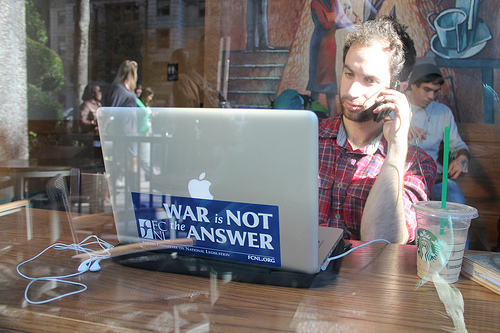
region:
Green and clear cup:
[405, 94, 485, 330]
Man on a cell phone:
[329, 15, 421, 189]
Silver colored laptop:
[90, 83, 337, 300]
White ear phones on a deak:
[16, 216, 136, 323]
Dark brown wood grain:
[400, 309, 417, 327]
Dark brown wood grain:
[348, 309, 378, 327]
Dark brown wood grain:
[363, 266, 406, 303]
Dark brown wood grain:
[287, 299, 332, 329]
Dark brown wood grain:
[248, 290, 297, 322]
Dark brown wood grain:
[173, 295, 241, 331]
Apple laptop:
[94, 103, 345, 287]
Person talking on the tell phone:
[317, 19, 438, 249]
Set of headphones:
[17, 228, 112, 305]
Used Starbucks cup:
[417, 122, 475, 287]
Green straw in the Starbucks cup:
[440, 123, 448, 244]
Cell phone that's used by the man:
[374, 78, 404, 119]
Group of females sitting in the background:
[70, 56, 154, 173]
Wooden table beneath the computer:
[1, 208, 498, 330]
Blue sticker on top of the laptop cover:
[127, 192, 282, 267]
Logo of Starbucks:
[412, 228, 440, 262]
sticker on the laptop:
[130, 188, 287, 268]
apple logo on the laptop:
[183, 167, 227, 204]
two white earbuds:
[12, 228, 118, 308]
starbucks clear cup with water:
[412, 120, 474, 291]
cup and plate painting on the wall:
[429, 10, 485, 61]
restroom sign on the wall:
[164, 60, 178, 82]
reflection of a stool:
[6, 158, 84, 238]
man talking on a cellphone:
[336, 16, 423, 247]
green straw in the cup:
[428, 124, 458, 205]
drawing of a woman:
[297, 4, 337, 98]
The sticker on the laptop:
[127, 186, 282, 271]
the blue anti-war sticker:
[125, 184, 285, 270]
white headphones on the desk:
[15, 226, 113, 310]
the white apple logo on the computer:
[182, 167, 219, 200]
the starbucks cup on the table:
[405, 204, 477, 289]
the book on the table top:
[465, 249, 498, 294]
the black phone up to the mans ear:
[373, 74, 405, 131]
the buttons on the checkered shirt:
[331, 176, 346, 224]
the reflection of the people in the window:
[69, 44, 219, 199]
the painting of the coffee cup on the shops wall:
[422, 1, 494, 58]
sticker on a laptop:
[131, 192, 281, 272]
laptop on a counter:
[97, 104, 343, 282]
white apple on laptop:
[184, 172, 217, 202]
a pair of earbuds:
[17, 230, 117, 305]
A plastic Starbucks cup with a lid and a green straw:
[411, 122, 468, 282]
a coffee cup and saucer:
[425, 10, 491, 60]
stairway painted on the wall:
[217, 46, 289, 113]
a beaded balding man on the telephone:
[319, 15, 439, 243]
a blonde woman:
[111, 58, 149, 205]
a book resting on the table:
[464, 251, 496, 295]